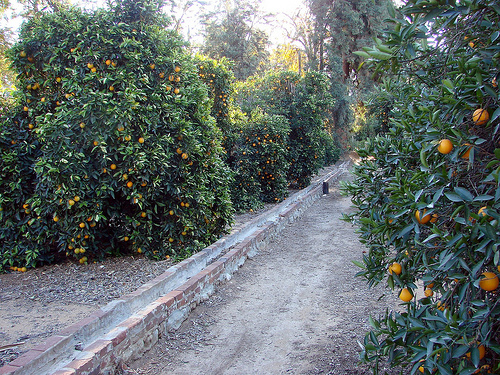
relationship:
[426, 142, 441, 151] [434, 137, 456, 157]
leaf covering orange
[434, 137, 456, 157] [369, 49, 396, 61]
orange located under a leaf